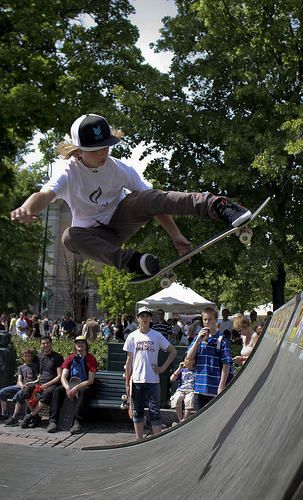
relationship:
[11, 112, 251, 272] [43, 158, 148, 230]
boy wearing shirt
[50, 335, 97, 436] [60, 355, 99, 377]
boy wearing shirt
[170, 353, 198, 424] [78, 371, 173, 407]
man on bench'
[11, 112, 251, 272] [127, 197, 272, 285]
boy on skateboard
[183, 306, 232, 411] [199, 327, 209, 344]
boy drinking soda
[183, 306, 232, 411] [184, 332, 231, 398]
boy wearing a blue shirt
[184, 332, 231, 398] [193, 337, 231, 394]
blue shirt has red stripes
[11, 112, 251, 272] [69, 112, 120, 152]
boy wearing hat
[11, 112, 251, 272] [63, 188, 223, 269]
boy wearing pants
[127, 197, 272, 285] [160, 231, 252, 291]
skateboard has wheels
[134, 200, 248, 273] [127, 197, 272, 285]
shoes are on skateboard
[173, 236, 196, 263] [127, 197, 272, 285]
hand touching skateboard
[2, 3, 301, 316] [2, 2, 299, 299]
trees have leaves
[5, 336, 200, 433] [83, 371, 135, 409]
people on bench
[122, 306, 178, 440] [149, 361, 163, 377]
person has hand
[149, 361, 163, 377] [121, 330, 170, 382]
hand on shirt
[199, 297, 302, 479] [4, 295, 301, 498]
shadow on ramp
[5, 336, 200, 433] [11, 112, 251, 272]
people are watching boy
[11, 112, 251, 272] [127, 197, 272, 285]
boy holding skateboard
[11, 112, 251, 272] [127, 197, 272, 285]
boy doing tricks on skateboard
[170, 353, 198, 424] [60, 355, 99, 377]
man wearing red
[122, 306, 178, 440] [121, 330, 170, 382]
person wearing white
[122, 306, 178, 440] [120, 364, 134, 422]
person holding skateboard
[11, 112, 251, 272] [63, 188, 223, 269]
boy wearing brown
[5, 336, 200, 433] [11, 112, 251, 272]
people watching boy